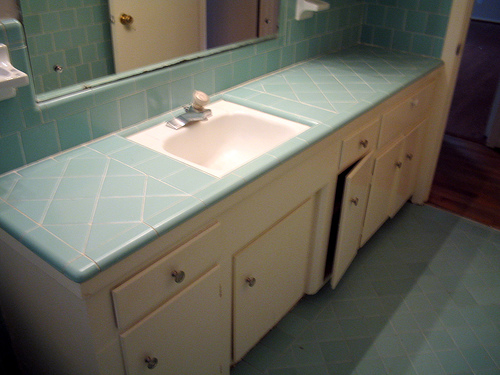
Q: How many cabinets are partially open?
A: One.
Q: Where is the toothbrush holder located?
A: To the left of the sink.